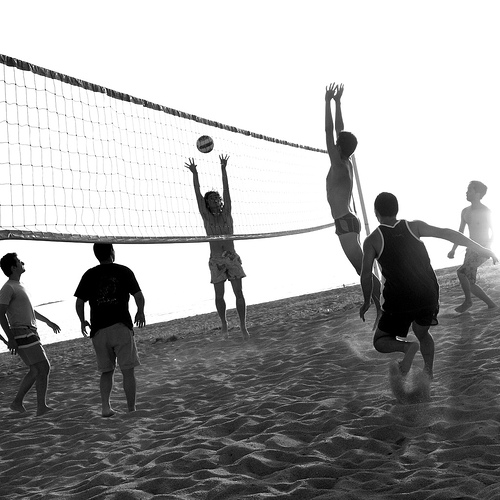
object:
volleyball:
[195, 133, 214, 154]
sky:
[240, 4, 499, 101]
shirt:
[376, 219, 441, 311]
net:
[45, 55, 197, 239]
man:
[321, 81, 387, 329]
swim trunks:
[205, 254, 247, 284]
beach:
[268, 394, 334, 478]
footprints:
[100, 434, 167, 472]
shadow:
[370, 413, 380, 423]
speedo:
[334, 212, 362, 236]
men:
[182, 152, 250, 339]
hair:
[337, 131, 358, 157]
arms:
[181, 154, 236, 174]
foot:
[369, 312, 384, 334]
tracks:
[242, 407, 309, 462]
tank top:
[380, 218, 403, 229]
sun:
[84, 12, 94, 19]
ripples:
[214, 385, 251, 415]